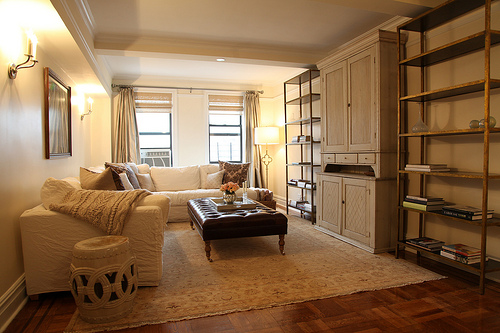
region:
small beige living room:
[53, 49, 434, 289]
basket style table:
[58, 227, 148, 317]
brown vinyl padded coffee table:
[172, 180, 297, 256]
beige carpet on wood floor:
[190, 257, 410, 307]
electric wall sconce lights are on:
[11, 22, 102, 127]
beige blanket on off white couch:
[45, 166, 150, 234]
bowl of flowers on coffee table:
[200, 177, 252, 207]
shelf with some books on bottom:
[391, 5, 491, 285]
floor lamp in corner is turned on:
[250, 100, 291, 201]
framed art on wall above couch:
[28, 67, 81, 164]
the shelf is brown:
[394, 6, 498, 295]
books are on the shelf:
[402, 99, 487, 269]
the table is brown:
[185, 183, 294, 257]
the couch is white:
[16, 143, 264, 288]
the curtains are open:
[108, 82, 267, 179]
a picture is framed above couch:
[37, 56, 97, 172]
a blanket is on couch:
[33, 171, 172, 240]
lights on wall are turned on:
[14, 20, 120, 135]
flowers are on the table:
[212, 172, 252, 212]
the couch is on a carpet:
[23, 151, 410, 321]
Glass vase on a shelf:
[409, 101, 429, 131]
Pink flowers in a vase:
[220, 180, 237, 192]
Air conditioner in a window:
[141, 148, 172, 168]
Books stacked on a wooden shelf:
[397, 171, 486, 220]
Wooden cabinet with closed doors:
[315, 171, 394, 252]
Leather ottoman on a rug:
[185, 197, 288, 234]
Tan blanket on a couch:
[51, 186, 145, 230]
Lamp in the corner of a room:
[252, 128, 282, 200]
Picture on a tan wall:
[43, 66, 77, 158]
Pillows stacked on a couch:
[78, 162, 162, 197]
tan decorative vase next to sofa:
[67, 237, 142, 322]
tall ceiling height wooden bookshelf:
[401, 21, 497, 182]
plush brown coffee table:
[181, 191, 300, 263]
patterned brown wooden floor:
[347, 295, 479, 331]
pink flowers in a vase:
[212, 179, 240, 206]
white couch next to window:
[145, 162, 218, 211]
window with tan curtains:
[108, 77, 261, 167]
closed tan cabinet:
[315, 50, 390, 182]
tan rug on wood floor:
[192, 273, 362, 326]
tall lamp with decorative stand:
[251, 118, 282, 200]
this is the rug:
[51, 199, 475, 321]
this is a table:
[183, 187, 297, 274]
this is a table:
[41, 213, 151, 322]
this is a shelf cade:
[398, 61, 498, 262]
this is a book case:
[276, 68, 358, 219]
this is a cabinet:
[306, 166, 396, 281]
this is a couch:
[101, 137, 289, 214]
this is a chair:
[26, 162, 177, 318]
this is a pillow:
[212, 152, 272, 202]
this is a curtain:
[83, 86, 166, 178]